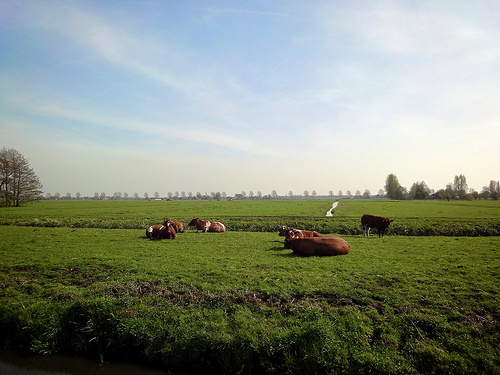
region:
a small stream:
[317, 190, 350, 220]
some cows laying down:
[120, 188, 355, 266]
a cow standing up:
[352, 211, 409, 247]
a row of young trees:
[36, 183, 382, 203]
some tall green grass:
[7, 295, 350, 372]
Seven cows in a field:
[141, 213, 391, 260]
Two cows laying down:
[146, 215, 183, 240]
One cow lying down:
[190, 213, 225, 233]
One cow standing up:
[361, 213, 392, 237]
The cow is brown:
[282, 234, 350, 257]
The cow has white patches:
[188, 215, 227, 232]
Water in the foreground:
[0, 343, 253, 373]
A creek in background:
[325, 200, 340, 215]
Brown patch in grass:
[122, 279, 359, 312]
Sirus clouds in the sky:
[1, 0, 497, 197]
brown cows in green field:
[261, 211, 346, 275]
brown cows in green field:
[183, 213, 221, 243]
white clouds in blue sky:
[77, 14, 124, 67]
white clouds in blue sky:
[261, 79, 331, 129]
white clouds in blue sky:
[18, 91, 56, 121]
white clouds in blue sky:
[135, 166, 170, 189]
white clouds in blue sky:
[394, 35, 445, 86]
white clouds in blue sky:
[251, 69, 301, 108]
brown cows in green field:
[133, 205, 354, 271]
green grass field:
[8, 190, 497, 373]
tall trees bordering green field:
[45, 184, 387, 200]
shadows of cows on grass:
[265, 233, 295, 261]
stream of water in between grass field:
[321, 195, 339, 219]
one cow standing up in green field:
[353, 208, 396, 242]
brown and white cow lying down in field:
[184, 214, 230, 236]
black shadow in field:
[6, 298, 391, 374]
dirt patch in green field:
[116, 280, 356, 315]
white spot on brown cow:
[201, 216, 214, 231]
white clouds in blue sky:
[44, 31, 111, 49]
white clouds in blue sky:
[205, 82, 290, 137]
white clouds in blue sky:
[370, 51, 428, 99]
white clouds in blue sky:
[58, 125, 140, 172]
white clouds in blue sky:
[161, 35, 253, 105]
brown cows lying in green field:
[268, 226, 356, 266]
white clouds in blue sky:
[90, 45, 144, 103]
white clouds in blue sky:
[58, 142, 132, 190]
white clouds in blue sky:
[128, 26, 188, 60]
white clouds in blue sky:
[331, 65, 385, 97]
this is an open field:
[55, 121, 433, 297]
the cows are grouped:
[126, 187, 314, 277]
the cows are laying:
[123, 186, 423, 282]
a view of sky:
[175, 63, 279, 155]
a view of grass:
[251, 283, 334, 350]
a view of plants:
[250, 313, 360, 361]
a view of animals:
[244, 208, 329, 266]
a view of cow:
[246, 160, 365, 256]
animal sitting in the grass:
[263, 207, 340, 277]